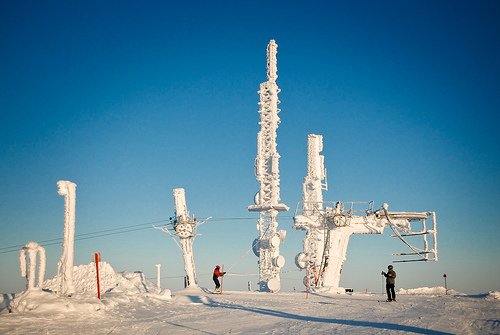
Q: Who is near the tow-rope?
A: Skiers.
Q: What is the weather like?
A: Sunny.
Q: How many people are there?
A: Two.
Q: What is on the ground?
A: Snow.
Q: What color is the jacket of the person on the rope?
A: Red.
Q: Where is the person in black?
A: To the right.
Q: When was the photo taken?
A: During the day.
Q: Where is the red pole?
A: On the left.